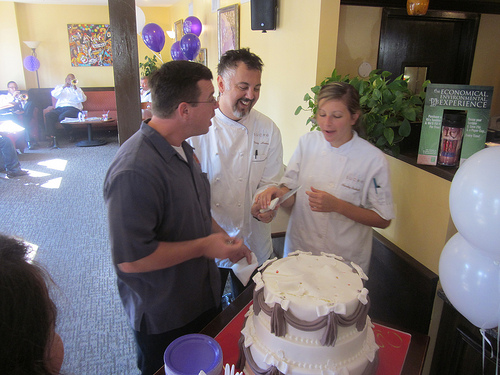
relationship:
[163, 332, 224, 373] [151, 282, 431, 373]
plates on table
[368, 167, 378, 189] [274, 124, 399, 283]
pen on shirt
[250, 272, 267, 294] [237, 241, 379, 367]
bow on cake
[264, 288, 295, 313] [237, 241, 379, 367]
bow on cake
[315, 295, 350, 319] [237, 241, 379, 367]
bow on cake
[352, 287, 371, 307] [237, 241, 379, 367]
bow on cake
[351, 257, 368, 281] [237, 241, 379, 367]
bow on cake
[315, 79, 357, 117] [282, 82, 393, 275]
hair of woman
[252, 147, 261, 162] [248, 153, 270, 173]
pen in pocket